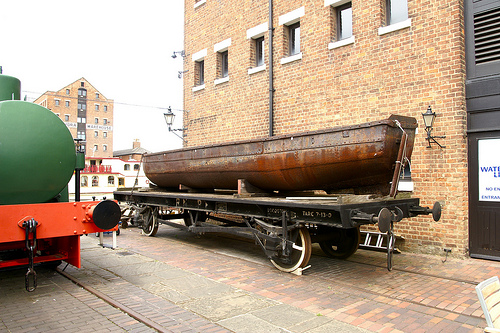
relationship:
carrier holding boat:
[109, 185, 445, 275] [143, 115, 419, 192]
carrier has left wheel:
[109, 185, 445, 275] [261, 219, 314, 271]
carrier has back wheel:
[109, 185, 445, 275] [135, 203, 161, 239]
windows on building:
[191, 1, 412, 93] [183, 1, 469, 257]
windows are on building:
[191, 1, 412, 93] [183, 1, 469, 257]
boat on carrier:
[143, 115, 419, 192] [109, 185, 445, 275]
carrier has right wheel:
[109, 185, 445, 275] [180, 199, 210, 232]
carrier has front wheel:
[109, 185, 445, 275] [261, 219, 314, 271]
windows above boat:
[191, 1, 412, 93] [143, 115, 419, 192]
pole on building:
[265, 1, 278, 139] [183, 1, 469, 257]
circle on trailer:
[90, 197, 122, 231] [0, 198, 121, 291]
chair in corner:
[474, 273, 500, 333] [441, 264, 500, 331]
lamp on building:
[416, 105, 447, 151] [183, 1, 469, 257]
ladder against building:
[360, 227, 406, 255] [183, 1, 469, 257]